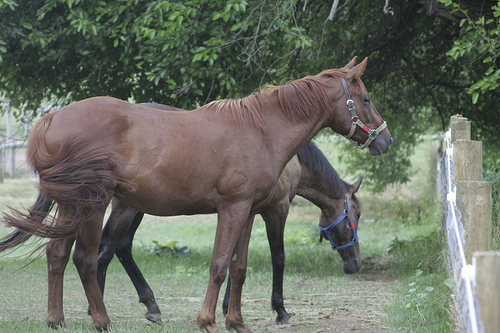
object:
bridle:
[340, 77, 388, 149]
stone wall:
[435, 114, 500, 333]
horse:
[27, 55, 393, 331]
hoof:
[140, 308, 167, 328]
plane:
[0, 47, 500, 250]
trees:
[0, 0, 500, 195]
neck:
[299, 148, 343, 210]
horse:
[264, 139, 366, 321]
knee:
[207, 257, 228, 289]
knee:
[228, 259, 246, 287]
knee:
[46, 239, 72, 277]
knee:
[72, 248, 101, 275]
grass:
[395, 220, 440, 324]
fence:
[437, 114, 500, 332]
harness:
[317, 192, 360, 270]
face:
[328, 196, 363, 274]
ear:
[350, 176, 362, 194]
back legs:
[71, 170, 114, 315]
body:
[25, 96, 279, 215]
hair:
[203, 69, 343, 135]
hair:
[297, 140, 354, 196]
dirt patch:
[298, 275, 440, 331]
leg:
[197, 199, 255, 332]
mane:
[296, 140, 356, 200]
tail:
[6, 114, 121, 246]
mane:
[200, 65, 346, 136]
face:
[337, 79, 393, 154]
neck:
[254, 71, 337, 165]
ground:
[0, 104, 437, 333]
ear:
[350, 56, 368, 79]